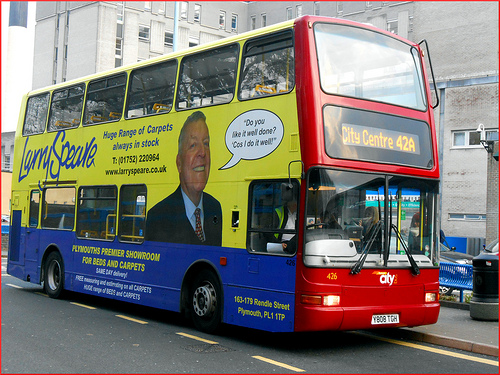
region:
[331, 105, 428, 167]
City Centre 42 A written on the bus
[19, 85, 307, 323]
Carpet advertisement on the side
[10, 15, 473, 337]
A double decker bus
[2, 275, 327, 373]
Black asphalt road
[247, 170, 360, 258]
Bus driver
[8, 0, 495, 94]
Buildings on the left side of the bus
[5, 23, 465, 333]
Route 42A bus going to City Centre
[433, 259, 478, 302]
Blue bench on the side walk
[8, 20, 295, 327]
Glass windows of the bus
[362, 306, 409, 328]
License plate number in the front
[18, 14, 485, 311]
a double decker bus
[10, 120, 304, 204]
the bus has advertisements on it.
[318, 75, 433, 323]
the front of the bus is red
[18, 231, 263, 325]
the bottom of the bus is blue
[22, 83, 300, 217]
the top of the bus is yellow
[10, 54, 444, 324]
the bus is not moving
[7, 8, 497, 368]
picture taken outdoors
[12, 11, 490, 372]
picture taken during the day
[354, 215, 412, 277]
windshield wipers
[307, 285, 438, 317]
the bus lights are on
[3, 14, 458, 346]
The bus has two seating areas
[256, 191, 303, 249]
The bus driver is stopped at the bus stop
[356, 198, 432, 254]
The people are getting on the bus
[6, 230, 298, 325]
The bottom on the bus is blue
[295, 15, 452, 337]
The front of the bus is red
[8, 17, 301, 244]
The side of the bus is yellow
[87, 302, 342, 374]
The lines on the street yellow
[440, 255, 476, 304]
The bench is the color blue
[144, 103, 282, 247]
An ad on the bus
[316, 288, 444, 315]
The head lights on the front of the bus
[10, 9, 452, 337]
This is a bus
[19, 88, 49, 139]
Window of a bus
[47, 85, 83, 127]
Window of a bus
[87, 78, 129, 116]
Window of a bus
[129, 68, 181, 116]
Window of a bus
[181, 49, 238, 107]
Window of a bus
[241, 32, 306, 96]
Window of a bus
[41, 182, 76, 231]
Window of a bus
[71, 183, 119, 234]
Window of a bus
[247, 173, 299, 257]
Window of a bus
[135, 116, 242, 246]
picture of a man on the side of the bus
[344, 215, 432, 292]
two windshield wipers on the windows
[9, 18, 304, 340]
large advertisement on the side of the bus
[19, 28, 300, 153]
row of six windows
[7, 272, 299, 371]
dotted line on the ground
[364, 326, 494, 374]
yellow line on the side of the road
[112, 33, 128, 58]
window on the side of the building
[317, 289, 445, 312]
two lights on the front of the bus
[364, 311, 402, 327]
black and white license plate